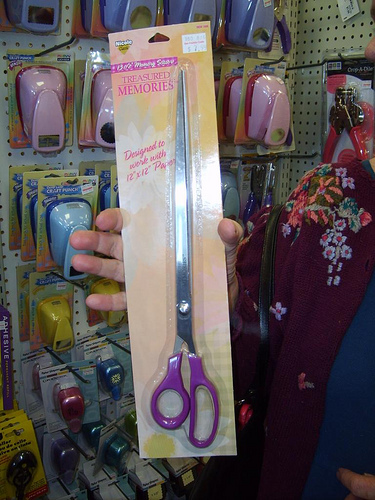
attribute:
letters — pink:
[116, 72, 177, 95]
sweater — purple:
[232, 161, 371, 498]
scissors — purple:
[148, 61, 241, 448]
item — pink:
[10, 59, 78, 155]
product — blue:
[17, 177, 102, 267]